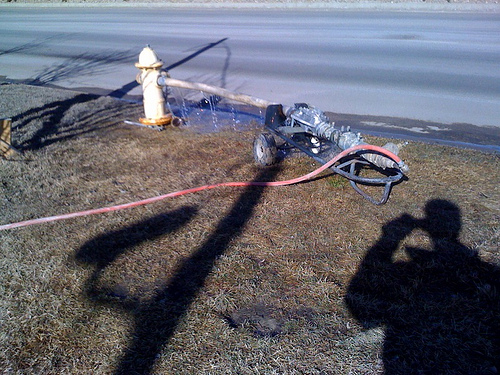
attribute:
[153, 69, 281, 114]
hose — short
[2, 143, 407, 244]
hose — long, thin, red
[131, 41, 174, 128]
hydrant — painted, faded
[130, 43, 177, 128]
fire hyrdrant — yellow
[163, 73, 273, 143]
thick hose — is thick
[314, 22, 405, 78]
pavement — wet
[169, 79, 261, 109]
hose — thick